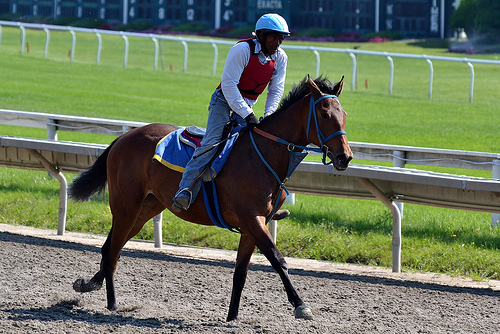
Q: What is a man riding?
A: A horse.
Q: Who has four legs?
A: The horse.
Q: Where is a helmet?
A: On man's head.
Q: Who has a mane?
A: The horse.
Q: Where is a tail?
A: On back of the horse.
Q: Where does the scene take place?
A: On horse track.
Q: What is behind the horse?
A: A fence.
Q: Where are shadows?
A: On the ground.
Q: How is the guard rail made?
A: Metal.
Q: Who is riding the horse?
A: A man.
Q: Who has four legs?
A: The horse.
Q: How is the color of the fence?
A: White.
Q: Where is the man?
A: On horse.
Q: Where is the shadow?
A: Under rail.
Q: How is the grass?
A: Green.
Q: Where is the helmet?
A: On rider.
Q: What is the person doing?
A: Riding the horse.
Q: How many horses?
A: One.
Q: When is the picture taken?
A: Daytime.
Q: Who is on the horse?
A: A person.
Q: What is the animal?
A: A horse.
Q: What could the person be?
A: A jockey.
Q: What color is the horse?
A: Brown.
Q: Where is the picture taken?
A: At a horse racing track.